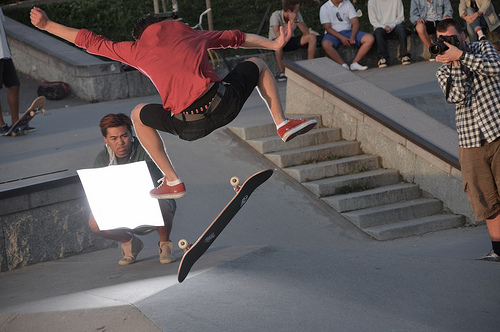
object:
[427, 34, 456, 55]
camera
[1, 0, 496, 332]
area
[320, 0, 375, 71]
man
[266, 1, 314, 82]
man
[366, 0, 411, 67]
man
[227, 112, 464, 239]
stairs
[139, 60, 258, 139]
black shorts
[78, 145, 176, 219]
shirt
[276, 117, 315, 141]
shoe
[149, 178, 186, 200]
shoe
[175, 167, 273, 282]
skateboard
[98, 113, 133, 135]
hair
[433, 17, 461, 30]
hair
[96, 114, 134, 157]
head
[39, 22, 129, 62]
arm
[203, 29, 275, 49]
arm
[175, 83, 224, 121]
belt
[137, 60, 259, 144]
shorts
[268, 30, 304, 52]
shorts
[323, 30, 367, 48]
shorts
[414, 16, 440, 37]
shorts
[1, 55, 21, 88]
shorts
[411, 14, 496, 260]
man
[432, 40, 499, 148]
checkered shirt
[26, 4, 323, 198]
person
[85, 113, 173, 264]
man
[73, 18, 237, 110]
shirt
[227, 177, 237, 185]
wheels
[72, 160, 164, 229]
paper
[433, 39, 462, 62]
hand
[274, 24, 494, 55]
stoop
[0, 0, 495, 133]
air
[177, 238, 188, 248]
wheel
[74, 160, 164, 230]
mirror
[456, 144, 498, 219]
shorts